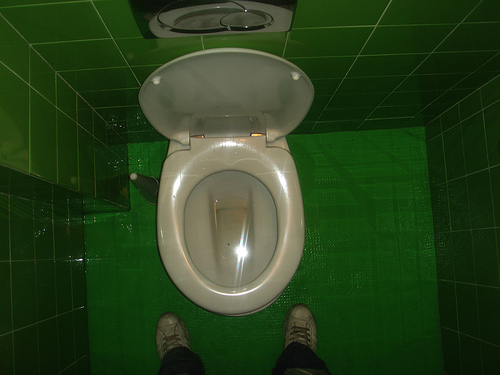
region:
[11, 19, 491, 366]
the bathroom is tiled green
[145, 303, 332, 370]
a man is standing in front of the toilet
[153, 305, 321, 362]
the person is wearing white shoes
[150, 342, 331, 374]
blue jeans are on the man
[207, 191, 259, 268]
water is in the toilet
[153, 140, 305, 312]
the seat of the toilet is down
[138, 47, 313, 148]
the lid of the toilet is up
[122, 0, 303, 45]
a mirror is above the toilet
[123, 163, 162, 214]
a cleaning brush holder is beside the toilet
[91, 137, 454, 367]
the floor tile is a brighter green than the walls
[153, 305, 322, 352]
Two white men's sneakers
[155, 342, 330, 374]
Cuffs of denim jeans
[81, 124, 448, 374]
Bright green tile floor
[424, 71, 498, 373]
Bright green tile wall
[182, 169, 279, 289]
Water inside of a toilet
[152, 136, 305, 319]
White seat on a toilet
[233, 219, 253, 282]
Camera flash glare on water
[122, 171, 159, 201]
Cone shaped item on floor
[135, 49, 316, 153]
White toilet lid sitting up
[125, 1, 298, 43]
Toilet paper dispenser on wall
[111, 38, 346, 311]
this is a toilet bowl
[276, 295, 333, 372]
a leg of a man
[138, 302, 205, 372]
a leg of a man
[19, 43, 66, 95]
this is a tile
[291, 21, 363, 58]
this is a tile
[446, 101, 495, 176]
this is a tile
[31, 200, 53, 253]
this is a tile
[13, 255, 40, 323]
this is a tile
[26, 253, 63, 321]
this is a tile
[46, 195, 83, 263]
this is a tile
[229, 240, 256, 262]
glare in the toilet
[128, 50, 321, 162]
toilet lid is up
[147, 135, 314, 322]
toilet seat is down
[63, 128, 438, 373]
green tile on the floor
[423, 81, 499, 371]
green tile on the wall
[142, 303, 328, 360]
two white shoes on the feet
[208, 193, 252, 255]
water in the toilet bowl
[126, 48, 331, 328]
white toilet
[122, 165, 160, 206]
something next to the toilet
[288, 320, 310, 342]
shoelaces on the shoe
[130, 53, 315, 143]
this is a toilet cover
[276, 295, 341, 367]
this is a leg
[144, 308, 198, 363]
this is a leg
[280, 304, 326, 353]
this is a shoe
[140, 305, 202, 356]
this is a shoe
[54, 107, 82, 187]
this is a tile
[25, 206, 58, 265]
this is a tile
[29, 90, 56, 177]
this is a tile